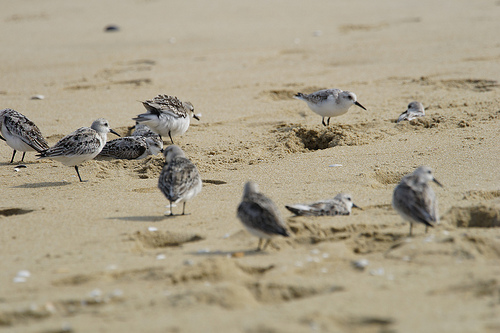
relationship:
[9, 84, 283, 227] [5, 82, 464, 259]
group of birds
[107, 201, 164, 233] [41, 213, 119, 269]
shadow on ground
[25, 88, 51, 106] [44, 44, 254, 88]
rock on sand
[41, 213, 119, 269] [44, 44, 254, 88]
ground covered in sand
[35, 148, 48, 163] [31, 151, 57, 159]
feathers on tail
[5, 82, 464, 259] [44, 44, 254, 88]
birds in sand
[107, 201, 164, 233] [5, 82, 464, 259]
shadow from birds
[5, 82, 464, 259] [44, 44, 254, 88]
birds on sand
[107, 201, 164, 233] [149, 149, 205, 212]
shadow of bird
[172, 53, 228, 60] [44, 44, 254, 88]
part of sand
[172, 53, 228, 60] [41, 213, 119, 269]
part of ground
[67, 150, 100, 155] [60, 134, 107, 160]
edge of wing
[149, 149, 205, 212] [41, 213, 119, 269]
bird on ground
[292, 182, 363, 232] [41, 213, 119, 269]
bird lying on ground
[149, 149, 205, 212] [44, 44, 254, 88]
bird in sand